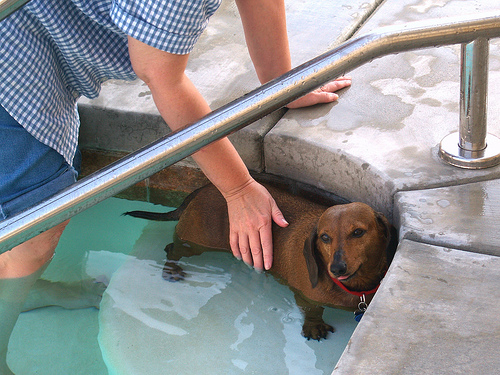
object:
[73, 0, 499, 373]
pavement